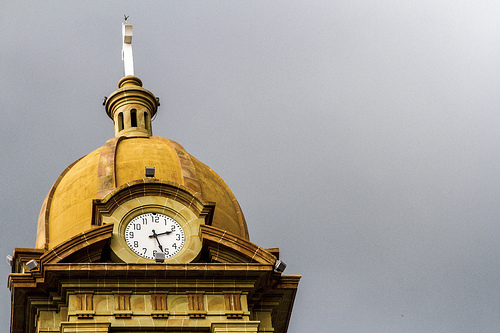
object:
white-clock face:
[120, 210, 187, 258]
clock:
[122, 211, 185, 262]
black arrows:
[150, 228, 167, 254]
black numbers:
[160, 247, 169, 256]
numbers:
[160, 217, 170, 225]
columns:
[78, 290, 243, 322]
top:
[99, 76, 159, 136]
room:
[100, 76, 160, 135]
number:
[129, 221, 143, 231]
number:
[168, 242, 176, 250]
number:
[175, 232, 181, 242]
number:
[168, 224, 177, 234]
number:
[129, 241, 140, 249]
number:
[140, 247, 150, 256]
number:
[151, 249, 160, 258]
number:
[129, 230, 135, 240]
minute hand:
[151, 230, 165, 252]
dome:
[32, 76, 250, 249]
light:
[272, 261, 285, 274]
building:
[4, 14, 302, 333]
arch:
[22, 222, 286, 278]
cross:
[118, 22, 135, 75]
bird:
[121, 13, 131, 22]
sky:
[0, 1, 499, 331]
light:
[21, 258, 38, 272]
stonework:
[222, 290, 245, 319]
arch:
[88, 177, 217, 228]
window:
[116, 112, 125, 131]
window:
[128, 107, 136, 127]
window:
[143, 110, 150, 130]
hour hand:
[148, 229, 171, 238]